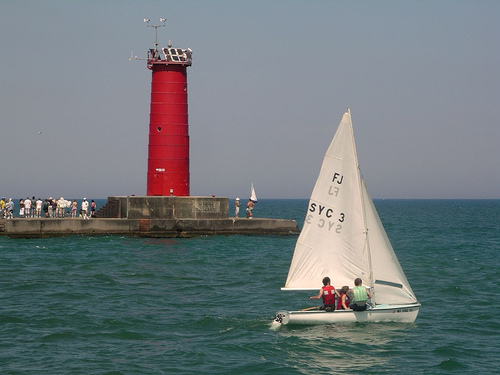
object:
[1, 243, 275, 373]
water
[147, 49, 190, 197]
light house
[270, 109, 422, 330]
sailboat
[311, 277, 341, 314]
man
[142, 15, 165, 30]
light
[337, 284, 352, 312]
woman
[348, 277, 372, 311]
man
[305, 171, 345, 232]
writing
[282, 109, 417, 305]
sails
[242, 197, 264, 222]
people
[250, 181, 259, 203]
sailboat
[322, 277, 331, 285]
hair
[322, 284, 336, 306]
life jacket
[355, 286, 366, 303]
life jacket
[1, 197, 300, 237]
pier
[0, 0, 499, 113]
sky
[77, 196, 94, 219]
people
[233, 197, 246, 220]
people